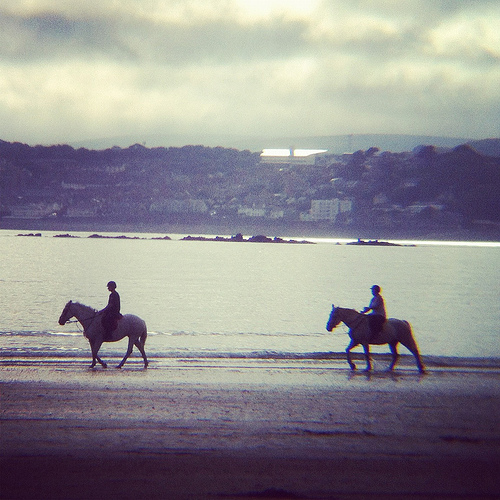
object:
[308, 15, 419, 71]
cloud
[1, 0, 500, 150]
sky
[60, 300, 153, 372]
horse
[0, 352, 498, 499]
beach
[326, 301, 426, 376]
horse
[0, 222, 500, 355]
water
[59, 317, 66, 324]
mouth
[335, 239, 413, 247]
island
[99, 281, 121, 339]
person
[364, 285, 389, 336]
person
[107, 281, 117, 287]
helmet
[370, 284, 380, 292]
helmet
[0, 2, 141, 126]
cloud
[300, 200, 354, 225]
building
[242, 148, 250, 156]
tree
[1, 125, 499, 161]
horizon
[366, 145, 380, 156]
tree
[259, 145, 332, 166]
building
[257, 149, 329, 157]
roof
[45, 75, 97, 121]
cloud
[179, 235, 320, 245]
island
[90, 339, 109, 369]
leg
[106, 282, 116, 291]
head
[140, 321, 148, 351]
tail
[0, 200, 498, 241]
shore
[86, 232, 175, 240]
island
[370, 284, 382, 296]
head